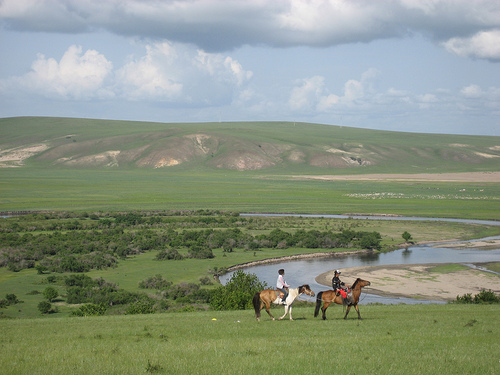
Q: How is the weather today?
A: It is cloudy.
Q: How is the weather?
A: It is cloudy.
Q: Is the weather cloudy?
A: Yes, it is cloudy.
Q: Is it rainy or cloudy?
A: It is cloudy.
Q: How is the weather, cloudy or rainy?
A: It is cloudy.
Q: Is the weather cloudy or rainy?
A: It is cloudy.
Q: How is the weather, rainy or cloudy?
A: It is cloudy.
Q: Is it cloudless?
A: No, it is cloudy.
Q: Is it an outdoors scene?
A: Yes, it is outdoors.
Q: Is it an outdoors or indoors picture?
A: It is outdoors.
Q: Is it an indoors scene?
A: No, it is outdoors.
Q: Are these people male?
A: No, they are both male and female.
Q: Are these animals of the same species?
A: Yes, all the animals are horses.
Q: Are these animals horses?
A: Yes, all the animals are horses.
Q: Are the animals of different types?
A: No, all the animals are horses.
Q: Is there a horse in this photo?
A: Yes, there is a horse.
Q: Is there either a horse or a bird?
A: Yes, there is a horse.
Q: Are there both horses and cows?
A: No, there is a horse but no cows.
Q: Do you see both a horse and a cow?
A: No, there is a horse but no cows.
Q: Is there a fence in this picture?
A: No, there are no fences.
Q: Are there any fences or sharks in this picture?
A: No, there are no fences or sharks.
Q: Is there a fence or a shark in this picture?
A: No, there are no fences or sharks.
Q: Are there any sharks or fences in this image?
A: No, there are no fences or sharks.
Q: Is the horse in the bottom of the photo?
A: Yes, the horse is in the bottom of the image.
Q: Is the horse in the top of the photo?
A: No, the horse is in the bottom of the image.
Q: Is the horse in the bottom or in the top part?
A: The horse is in the bottom of the image.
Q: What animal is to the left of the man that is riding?
A: The animal is a horse.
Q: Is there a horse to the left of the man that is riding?
A: Yes, there is a horse to the left of the man.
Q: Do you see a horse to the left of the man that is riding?
A: Yes, there is a horse to the left of the man.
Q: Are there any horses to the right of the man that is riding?
A: No, the horse is to the left of the man.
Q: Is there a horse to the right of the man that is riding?
A: No, the horse is to the left of the man.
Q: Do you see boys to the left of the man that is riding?
A: No, there is a horse to the left of the man.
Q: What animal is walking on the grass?
A: The horse is walking on the grass.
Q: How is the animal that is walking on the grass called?
A: The animal is a horse.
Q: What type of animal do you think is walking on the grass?
A: The animal is a horse.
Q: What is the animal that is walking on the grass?
A: The animal is a horse.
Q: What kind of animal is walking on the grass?
A: The animal is a horse.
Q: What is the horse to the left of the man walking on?
A: The horse is walking on the grass.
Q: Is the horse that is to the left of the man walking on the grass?
A: Yes, the horse is walking on the grass.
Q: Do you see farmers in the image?
A: No, there are no farmers.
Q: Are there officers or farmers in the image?
A: No, there are no farmers or officers.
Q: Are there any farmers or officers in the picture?
A: No, there are no farmers or officers.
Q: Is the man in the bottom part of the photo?
A: Yes, the man is in the bottom of the image.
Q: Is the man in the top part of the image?
A: No, the man is in the bottom of the image.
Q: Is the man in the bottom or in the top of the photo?
A: The man is in the bottom of the image.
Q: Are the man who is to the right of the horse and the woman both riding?
A: Yes, both the man and the woman are riding.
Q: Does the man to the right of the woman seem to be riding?
A: Yes, the man is riding.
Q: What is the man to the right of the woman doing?
A: The man is riding.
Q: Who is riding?
A: The man is riding.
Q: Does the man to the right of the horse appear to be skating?
A: No, the man is riding.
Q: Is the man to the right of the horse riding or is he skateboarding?
A: The man is riding.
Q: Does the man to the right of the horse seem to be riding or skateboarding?
A: The man is riding.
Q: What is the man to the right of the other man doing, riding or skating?
A: The man is riding.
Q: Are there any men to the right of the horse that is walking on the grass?
A: Yes, there is a man to the right of the horse.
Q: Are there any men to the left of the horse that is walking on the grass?
A: No, the man is to the right of the horse.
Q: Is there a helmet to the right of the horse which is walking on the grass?
A: No, there is a man to the right of the horse.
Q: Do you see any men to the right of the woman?
A: Yes, there is a man to the right of the woman.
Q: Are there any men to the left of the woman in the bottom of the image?
A: No, the man is to the right of the woman.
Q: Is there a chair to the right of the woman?
A: No, there is a man to the right of the woman.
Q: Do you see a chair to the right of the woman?
A: No, there is a man to the right of the woman.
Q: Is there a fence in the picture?
A: No, there are no fences.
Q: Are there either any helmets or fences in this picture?
A: No, there are no fences or helmets.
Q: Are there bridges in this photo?
A: No, there are no bridges.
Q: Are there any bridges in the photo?
A: No, there are no bridges.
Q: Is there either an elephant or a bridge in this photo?
A: No, there are no bridges or elephants.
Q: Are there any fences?
A: No, there are no fences.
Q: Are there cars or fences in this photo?
A: No, there are no fences or cars.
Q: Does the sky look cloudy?
A: Yes, the sky is cloudy.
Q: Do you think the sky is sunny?
A: No, the sky is cloudy.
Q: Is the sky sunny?
A: No, the sky is cloudy.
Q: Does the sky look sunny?
A: No, the sky is cloudy.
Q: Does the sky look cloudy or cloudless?
A: The sky is cloudy.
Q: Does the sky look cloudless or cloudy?
A: The sky is cloudy.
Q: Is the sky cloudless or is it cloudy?
A: The sky is cloudy.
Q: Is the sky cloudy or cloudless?
A: The sky is cloudy.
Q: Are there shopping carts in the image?
A: No, there are no shopping carts.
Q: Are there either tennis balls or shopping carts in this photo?
A: No, there are no shopping carts or tennis balls.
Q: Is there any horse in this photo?
A: Yes, there is a horse.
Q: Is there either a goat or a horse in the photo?
A: Yes, there is a horse.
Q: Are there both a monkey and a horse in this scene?
A: No, there is a horse but no monkeys.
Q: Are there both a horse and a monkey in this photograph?
A: No, there is a horse but no monkeys.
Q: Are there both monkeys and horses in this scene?
A: No, there is a horse but no monkeys.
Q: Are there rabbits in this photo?
A: No, there are no rabbits.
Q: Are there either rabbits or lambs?
A: No, there are no rabbits or lambs.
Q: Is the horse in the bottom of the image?
A: Yes, the horse is in the bottom of the image.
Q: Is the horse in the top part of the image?
A: No, the horse is in the bottom of the image.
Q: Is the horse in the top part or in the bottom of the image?
A: The horse is in the bottom of the image.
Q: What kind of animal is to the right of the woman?
A: The animal is a horse.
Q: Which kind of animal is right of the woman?
A: The animal is a horse.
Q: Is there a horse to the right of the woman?
A: Yes, there is a horse to the right of the woman.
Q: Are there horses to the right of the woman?
A: Yes, there is a horse to the right of the woman.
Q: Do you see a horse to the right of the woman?
A: Yes, there is a horse to the right of the woman.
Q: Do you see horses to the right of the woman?
A: Yes, there is a horse to the right of the woman.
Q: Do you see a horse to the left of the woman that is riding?
A: No, the horse is to the right of the woman.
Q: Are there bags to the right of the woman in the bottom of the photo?
A: No, there is a horse to the right of the woman.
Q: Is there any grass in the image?
A: Yes, there is grass.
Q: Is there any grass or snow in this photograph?
A: Yes, there is grass.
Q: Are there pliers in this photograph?
A: No, there are no pliers.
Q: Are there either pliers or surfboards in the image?
A: No, there are no pliers or surfboards.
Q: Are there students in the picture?
A: No, there are no students.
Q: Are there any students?
A: No, there are no students.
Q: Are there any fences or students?
A: No, there are no students or fences.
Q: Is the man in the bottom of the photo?
A: Yes, the man is in the bottom of the image.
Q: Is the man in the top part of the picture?
A: No, the man is in the bottom of the image.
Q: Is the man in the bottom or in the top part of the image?
A: The man is in the bottom of the image.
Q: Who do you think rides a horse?
A: The man rides a horse.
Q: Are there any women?
A: Yes, there is a woman.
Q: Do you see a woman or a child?
A: Yes, there is a woman.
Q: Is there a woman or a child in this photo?
A: Yes, there is a woman.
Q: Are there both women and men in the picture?
A: Yes, there are both a woman and a man.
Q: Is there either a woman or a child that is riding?
A: Yes, the woman is riding.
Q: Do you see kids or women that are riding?
A: Yes, the woman is riding.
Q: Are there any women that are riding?
A: Yes, there is a woman that is riding.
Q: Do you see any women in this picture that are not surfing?
A: Yes, there is a woman that is riding .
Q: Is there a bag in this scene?
A: No, there are no bags.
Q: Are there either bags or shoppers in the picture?
A: No, there are no bags or shoppers.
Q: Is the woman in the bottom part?
A: Yes, the woman is in the bottom of the image.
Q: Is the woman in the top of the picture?
A: No, the woman is in the bottom of the image.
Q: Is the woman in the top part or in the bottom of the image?
A: The woman is in the bottom of the image.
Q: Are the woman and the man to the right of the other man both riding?
A: Yes, both the woman and the man are riding.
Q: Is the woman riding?
A: Yes, the woman is riding.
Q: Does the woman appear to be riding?
A: Yes, the woman is riding.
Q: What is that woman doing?
A: The woman is riding.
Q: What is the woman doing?
A: The woman is riding.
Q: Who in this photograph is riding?
A: The woman is riding.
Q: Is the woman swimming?
A: No, the woman is riding.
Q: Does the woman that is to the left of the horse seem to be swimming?
A: No, the woman is riding.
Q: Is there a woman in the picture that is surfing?
A: No, there is a woman but she is riding.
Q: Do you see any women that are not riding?
A: No, there is a woman but she is riding.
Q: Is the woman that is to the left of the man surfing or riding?
A: The woman is riding.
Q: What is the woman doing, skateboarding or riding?
A: The woman is riding.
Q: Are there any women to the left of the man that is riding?
A: Yes, there is a woman to the left of the man.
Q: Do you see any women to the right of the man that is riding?
A: No, the woman is to the left of the man.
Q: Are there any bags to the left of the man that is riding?
A: No, there is a woman to the left of the man.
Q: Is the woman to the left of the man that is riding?
A: Yes, the woman is to the left of the man.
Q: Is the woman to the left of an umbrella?
A: No, the woman is to the left of the man.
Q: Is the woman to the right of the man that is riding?
A: No, the woman is to the left of the man.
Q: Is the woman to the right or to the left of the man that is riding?
A: The woman is to the left of the man.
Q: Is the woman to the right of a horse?
A: No, the woman is to the left of a horse.